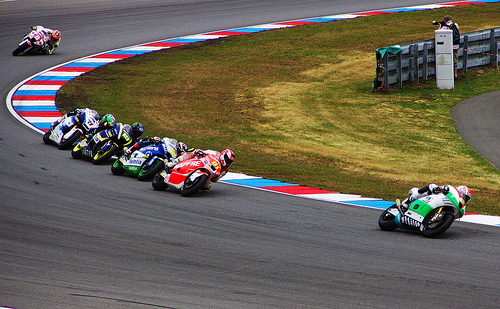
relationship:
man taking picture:
[430, 16, 463, 68] [419, 14, 454, 82]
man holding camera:
[430, 16, 463, 68] [432, 19, 440, 29]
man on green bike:
[451, 180, 471, 204] [442, 180, 467, 214]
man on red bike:
[216, 142, 233, 173] [203, 142, 234, 172]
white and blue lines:
[129, 34, 171, 50] [124, 33, 147, 55]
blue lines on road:
[234, 26, 254, 36] [239, 26, 259, 34]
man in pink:
[442, 30, 455, 53] [436, 25, 458, 49]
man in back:
[12, 19, 73, 55] [8, 25, 56, 60]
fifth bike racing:
[53, 105, 91, 151] [48, 94, 87, 145]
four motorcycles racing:
[52, 102, 236, 195] [42, 118, 239, 195]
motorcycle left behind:
[12, 17, 63, 60] [17, 18, 70, 64]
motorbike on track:
[173, 149, 213, 195] [169, 150, 212, 194]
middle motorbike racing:
[128, 130, 161, 191] [128, 130, 166, 187]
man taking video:
[426, 16, 453, 33] [430, 9, 449, 32]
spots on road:
[12, 148, 46, 192] [17, 155, 64, 207]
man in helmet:
[130, 118, 142, 135] [130, 117, 141, 135]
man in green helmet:
[100, 107, 113, 126] [100, 107, 113, 129]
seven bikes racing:
[19, 16, 474, 212] [10, 12, 467, 213]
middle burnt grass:
[254, 57, 294, 76] [240, 50, 282, 88]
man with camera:
[430, 14, 462, 88] [432, 12, 464, 90]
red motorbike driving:
[177, 144, 239, 207] [173, 146, 231, 194]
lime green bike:
[120, 139, 160, 178] [114, 150, 154, 176]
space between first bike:
[240, 162, 371, 229] [241, 155, 381, 231]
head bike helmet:
[455, 176, 470, 200] [452, 180, 470, 202]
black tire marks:
[19, 190, 191, 280] [7, 217, 215, 304]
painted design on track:
[239, 167, 297, 195] [244, 173, 295, 202]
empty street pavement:
[82, 14, 163, 31] [81, 14, 155, 35]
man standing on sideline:
[430, 15, 460, 76] [418, 16, 476, 94]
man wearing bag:
[450, 26, 464, 51] [446, 26, 459, 49]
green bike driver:
[158, 132, 182, 154] [157, 134, 181, 158]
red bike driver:
[208, 150, 235, 173] [209, 150, 237, 170]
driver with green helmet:
[89, 105, 111, 129] [85, 101, 114, 137]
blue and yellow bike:
[83, 124, 123, 156] [79, 123, 130, 165]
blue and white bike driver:
[62, 99, 90, 132] [64, 97, 92, 129]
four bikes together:
[52, 102, 236, 195] [34, 104, 228, 218]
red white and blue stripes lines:
[282, 16, 386, 25] [275, 13, 353, 23]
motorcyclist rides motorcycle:
[408, 174, 475, 203] [375, 187, 467, 241]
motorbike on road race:
[162, 153, 222, 191] [6, 104, 327, 271]